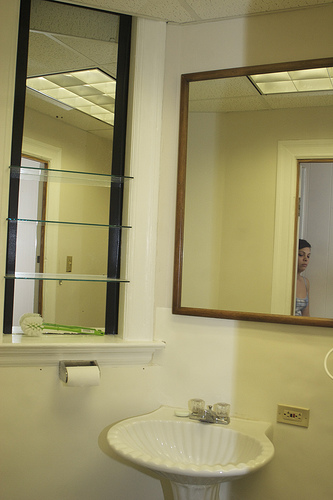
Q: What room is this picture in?
A: It is at the bathroom.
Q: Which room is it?
A: It is a bathroom.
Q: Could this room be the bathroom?
A: Yes, it is the bathroom.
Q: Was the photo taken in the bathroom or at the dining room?
A: It was taken at the bathroom.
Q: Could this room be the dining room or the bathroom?
A: It is the bathroom.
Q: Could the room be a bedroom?
A: No, it is a bathroom.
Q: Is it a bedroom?
A: No, it is a bathroom.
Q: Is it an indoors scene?
A: Yes, it is indoors.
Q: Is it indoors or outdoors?
A: It is indoors.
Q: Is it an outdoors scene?
A: No, it is indoors.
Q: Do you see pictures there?
A: No, there are no pictures.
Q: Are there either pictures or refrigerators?
A: No, there are no pictures or refrigerators.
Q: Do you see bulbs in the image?
A: No, there are no bulbs.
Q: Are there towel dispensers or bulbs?
A: No, there are no bulbs or towel dispensers.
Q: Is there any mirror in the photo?
A: Yes, there is a mirror.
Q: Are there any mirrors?
A: Yes, there is a mirror.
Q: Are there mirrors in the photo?
A: Yes, there is a mirror.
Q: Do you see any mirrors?
A: Yes, there is a mirror.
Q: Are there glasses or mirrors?
A: Yes, there is a mirror.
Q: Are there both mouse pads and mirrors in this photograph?
A: No, there is a mirror but no mouse pads.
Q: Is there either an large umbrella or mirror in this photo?
A: Yes, there is a large mirror.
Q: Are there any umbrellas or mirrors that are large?
A: Yes, the mirror is large.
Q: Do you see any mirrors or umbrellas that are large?
A: Yes, the mirror is large.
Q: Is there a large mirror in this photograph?
A: Yes, there is a large mirror.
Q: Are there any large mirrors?
A: Yes, there is a large mirror.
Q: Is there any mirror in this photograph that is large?
A: Yes, there is a mirror that is large.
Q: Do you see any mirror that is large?
A: Yes, there is a mirror that is large.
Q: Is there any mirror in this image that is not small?
A: Yes, there is a large mirror.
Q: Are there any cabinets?
A: No, there are no cabinets.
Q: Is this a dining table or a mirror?
A: This is a mirror.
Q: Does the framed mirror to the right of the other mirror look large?
A: Yes, the mirror is large.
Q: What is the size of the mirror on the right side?
A: The mirror is large.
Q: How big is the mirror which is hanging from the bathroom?
A: The mirror is large.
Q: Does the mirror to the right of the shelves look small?
A: No, the mirror is large.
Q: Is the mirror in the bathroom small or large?
A: The mirror is large.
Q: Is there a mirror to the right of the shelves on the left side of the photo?
A: Yes, there is a mirror to the right of the shelves.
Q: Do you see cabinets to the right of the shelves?
A: No, there is a mirror to the right of the shelves.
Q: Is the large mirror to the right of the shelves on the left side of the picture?
A: Yes, the mirror is to the right of the shelves.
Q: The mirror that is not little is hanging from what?
A: The mirror is hanging from the bathroom.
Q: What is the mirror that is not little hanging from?
A: The mirror is hanging from the bathroom.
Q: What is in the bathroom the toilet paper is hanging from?
A: The mirror is in the bathroom.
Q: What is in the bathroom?
A: The mirror is in the bathroom.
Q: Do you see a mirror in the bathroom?
A: Yes, there is a mirror in the bathroom.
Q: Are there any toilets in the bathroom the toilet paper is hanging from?
A: No, there is a mirror in the bathroom.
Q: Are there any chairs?
A: No, there are no chairs.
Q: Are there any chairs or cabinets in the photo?
A: No, there are no chairs or cabinets.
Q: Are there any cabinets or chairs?
A: No, there are no chairs or cabinets.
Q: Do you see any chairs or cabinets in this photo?
A: No, there are no chairs or cabinets.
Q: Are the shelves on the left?
A: Yes, the shelves are on the left of the image.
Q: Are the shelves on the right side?
A: No, the shelves are on the left of the image.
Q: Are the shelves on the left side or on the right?
A: The shelves are on the left of the image.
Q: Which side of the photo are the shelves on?
A: The shelves are on the left of the image.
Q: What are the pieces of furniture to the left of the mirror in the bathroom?
A: The pieces of furniture are shelves.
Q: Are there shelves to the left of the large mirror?
A: Yes, there are shelves to the left of the mirror.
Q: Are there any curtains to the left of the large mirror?
A: No, there are shelves to the left of the mirror.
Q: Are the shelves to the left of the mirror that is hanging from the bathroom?
A: Yes, the shelves are to the left of the mirror.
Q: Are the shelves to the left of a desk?
A: No, the shelves are to the left of the mirror.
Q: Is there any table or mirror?
A: Yes, there is a mirror.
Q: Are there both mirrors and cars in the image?
A: No, there is a mirror but no cars.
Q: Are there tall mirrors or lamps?
A: Yes, there is a tall mirror.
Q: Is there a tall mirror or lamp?
A: Yes, there is a tall mirror.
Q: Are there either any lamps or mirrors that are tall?
A: Yes, the mirror is tall.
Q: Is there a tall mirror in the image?
A: Yes, there is a tall mirror.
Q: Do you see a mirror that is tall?
A: Yes, there is a mirror that is tall.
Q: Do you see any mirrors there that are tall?
A: Yes, there is a mirror that is tall.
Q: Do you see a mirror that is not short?
A: Yes, there is a tall mirror.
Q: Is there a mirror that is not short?
A: Yes, there is a tall mirror.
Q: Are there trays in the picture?
A: No, there are no trays.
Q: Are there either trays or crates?
A: No, there are no trays or crates.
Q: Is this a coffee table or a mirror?
A: This is a mirror.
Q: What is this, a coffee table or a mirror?
A: This is a mirror.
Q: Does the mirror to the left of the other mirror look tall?
A: Yes, the mirror is tall.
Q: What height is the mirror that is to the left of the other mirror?
A: The mirror is tall.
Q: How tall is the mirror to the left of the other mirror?
A: The mirror is tall.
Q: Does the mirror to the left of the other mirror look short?
A: No, the mirror is tall.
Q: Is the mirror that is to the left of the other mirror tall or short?
A: The mirror is tall.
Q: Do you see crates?
A: No, there are no crates.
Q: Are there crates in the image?
A: No, there are no crates.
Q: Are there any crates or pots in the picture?
A: No, there are no crates or pots.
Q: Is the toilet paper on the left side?
A: Yes, the toilet paper is on the left of the image.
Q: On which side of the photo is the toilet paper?
A: The toilet paper is on the left of the image.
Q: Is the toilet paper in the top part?
A: No, the toilet paper is in the bottom of the image.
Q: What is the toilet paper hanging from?
A: The toilet paper is hanging from the bathroom.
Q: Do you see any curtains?
A: No, there are no curtains.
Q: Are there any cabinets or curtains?
A: No, there are no curtains or cabinets.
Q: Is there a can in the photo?
A: No, there are no cans.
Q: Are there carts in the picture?
A: No, there are no carts.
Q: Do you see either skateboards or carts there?
A: No, there are no carts or skateboards.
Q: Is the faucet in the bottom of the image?
A: Yes, the faucet is in the bottom of the image.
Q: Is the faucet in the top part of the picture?
A: No, the faucet is in the bottom of the image.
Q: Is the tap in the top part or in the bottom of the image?
A: The tap is in the bottom of the image.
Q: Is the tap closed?
A: Yes, the tap is closed.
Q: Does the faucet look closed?
A: Yes, the faucet is closed.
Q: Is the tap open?
A: No, the tap is closed.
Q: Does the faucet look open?
A: No, the faucet is closed.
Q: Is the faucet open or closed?
A: The faucet is closed.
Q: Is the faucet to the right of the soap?
A: Yes, the faucet is to the right of the soap.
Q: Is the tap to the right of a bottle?
A: No, the tap is to the right of the soap.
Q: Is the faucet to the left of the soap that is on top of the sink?
A: No, the faucet is to the right of the soap.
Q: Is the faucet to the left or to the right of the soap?
A: The faucet is to the right of the soap.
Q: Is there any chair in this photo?
A: No, there are no chairs.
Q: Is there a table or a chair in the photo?
A: No, there are no chairs or tables.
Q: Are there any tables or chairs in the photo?
A: No, there are no chairs or tables.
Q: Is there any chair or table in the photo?
A: No, there are no chairs or tables.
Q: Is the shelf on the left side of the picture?
A: Yes, the shelf is on the left of the image.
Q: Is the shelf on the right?
A: No, the shelf is on the left of the image.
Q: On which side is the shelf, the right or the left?
A: The shelf is on the left of the image.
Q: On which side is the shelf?
A: The shelf is on the left of the image.